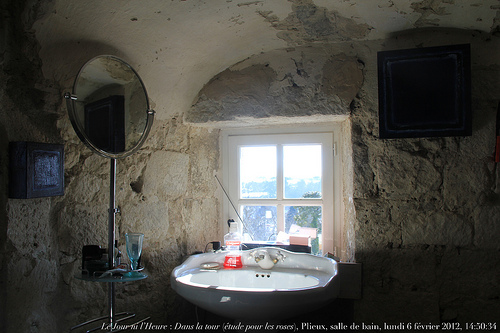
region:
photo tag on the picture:
[99, 322, 498, 331]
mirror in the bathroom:
[60, 37, 162, 177]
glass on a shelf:
[116, 223, 144, 283]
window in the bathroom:
[219, 123, 334, 255]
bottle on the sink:
[217, 214, 242, 271]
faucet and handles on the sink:
[239, 245, 291, 269]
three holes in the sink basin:
[254, 269, 276, 285]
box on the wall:
[356, 30, 489, 144]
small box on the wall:
[7, 136, 71, 204]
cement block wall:
[361, 165, 486, 327]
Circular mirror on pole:
[68, 57, 151, 149]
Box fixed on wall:
[1, 138, 66, 199]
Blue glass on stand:
[125, 231, 149, 276]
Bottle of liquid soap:
[223, 223, 243, 270]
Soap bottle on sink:
[222, 220, 241, 270]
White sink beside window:
[170, 245, 344, 325]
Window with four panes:
[236, 148, 333, 253]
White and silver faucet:
[248, 248, 286, 268]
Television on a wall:
[378, 43, 478, 137]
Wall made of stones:
[1, 5, 496, 331]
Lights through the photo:
[228, 152, 328, 202]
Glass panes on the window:
[241, 154, 306, 197]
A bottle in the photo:
[217, 216, 244, 266]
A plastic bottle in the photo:
[224, 207, 243, 269]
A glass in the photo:
[125, 227, 147, 280]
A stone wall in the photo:
[402, 137, 454, 249]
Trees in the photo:
[250, 169, 337, 226]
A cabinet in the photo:
[23, 136, 66, 199]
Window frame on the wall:
[212, 143, 239, 240]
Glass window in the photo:
[227, 139, 329, 246]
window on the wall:
[186, 120, 358, 262]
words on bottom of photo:
[95, 317, 496, 332]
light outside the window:
[243, 152, 271, 183]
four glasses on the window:
[233, 153, 322, 242]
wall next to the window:
[370, 161, 423, 212]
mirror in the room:
[71, 50, 188, 165]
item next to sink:
[215, 220, 255, 275]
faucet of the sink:
[241, 235, 283, 279]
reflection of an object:
[90, 80, 137, 136]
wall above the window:
[210, 48, 329, 108]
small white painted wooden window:
[221, 120, 342, 258]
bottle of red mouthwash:
[222, 220, 244, 271]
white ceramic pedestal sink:
[168, 246, 338, 329]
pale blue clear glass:
[124, 228, 144, 276]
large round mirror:
[70, 53, 150, 155]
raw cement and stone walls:
[1, 36, 498, 331]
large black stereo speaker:
[374, 36, 486, 141]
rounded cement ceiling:
[0, 0, 499, 115]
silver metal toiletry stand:
[66, 47, 152, 329]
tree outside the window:
[295, 189, 322, 254]